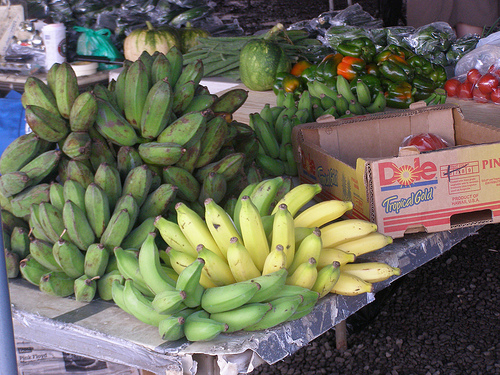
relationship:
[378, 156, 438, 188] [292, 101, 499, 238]
dole on box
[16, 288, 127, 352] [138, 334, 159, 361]
table top covered in plastic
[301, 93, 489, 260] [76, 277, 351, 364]
box on table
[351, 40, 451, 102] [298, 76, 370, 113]
peppers next to bananas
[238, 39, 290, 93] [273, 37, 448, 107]
watermelon next to peppers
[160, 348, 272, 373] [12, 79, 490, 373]
corner of table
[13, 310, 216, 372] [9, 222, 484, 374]
edge on table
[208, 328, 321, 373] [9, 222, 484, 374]
edge on table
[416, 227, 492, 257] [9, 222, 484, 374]
edge on table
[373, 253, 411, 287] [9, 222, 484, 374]
edge on table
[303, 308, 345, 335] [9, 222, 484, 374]
edge on table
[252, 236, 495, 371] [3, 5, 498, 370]
gravel under table